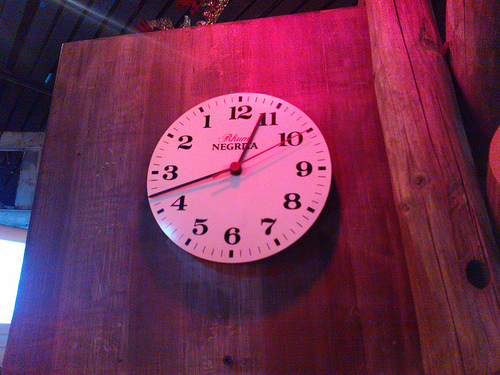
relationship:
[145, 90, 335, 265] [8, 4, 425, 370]
clock on wall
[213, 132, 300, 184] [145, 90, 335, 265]
hand on clock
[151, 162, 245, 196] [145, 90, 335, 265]
hand on clock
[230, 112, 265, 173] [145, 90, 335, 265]
hand on clock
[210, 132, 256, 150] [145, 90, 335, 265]
words on clock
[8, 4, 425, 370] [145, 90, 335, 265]
wall with clock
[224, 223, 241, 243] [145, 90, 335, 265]
6 on clock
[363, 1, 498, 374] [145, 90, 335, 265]
post near clock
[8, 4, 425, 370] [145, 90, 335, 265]
wall behind clock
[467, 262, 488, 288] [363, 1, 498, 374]
hole in post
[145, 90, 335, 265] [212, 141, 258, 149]
clock has writing